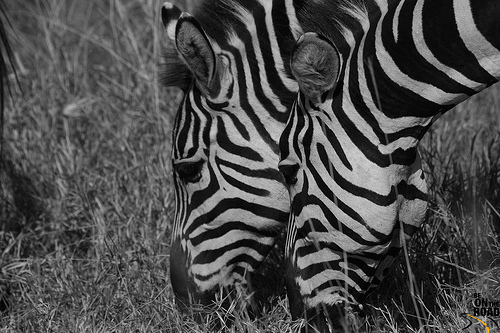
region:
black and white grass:
[43, 222, 133, 322]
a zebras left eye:
[164, 138, 211, 192]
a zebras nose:
[136, 187, 263, 325]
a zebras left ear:
[282, 43, 332, 98]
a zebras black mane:
[199, 10, 249, 27]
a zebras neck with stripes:
[370, 55, 497, 93]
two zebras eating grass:
[150, 22, 476, 312]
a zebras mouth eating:
[295, 295, 355, 328]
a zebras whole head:
[265, 111, 435, 329]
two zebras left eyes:
[157, 140, 322, 193]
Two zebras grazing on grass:
[156, 4, 379, 330]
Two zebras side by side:
[152, 5, 372, 325]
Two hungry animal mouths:
[155, 198, 401, 321]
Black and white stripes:
[340, 35, 415, 145]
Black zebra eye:
[163, 150, 211, 193]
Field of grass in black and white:
[43, 122, 141, 297]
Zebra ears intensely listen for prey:
[147, 10, 278, 105]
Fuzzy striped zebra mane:
[287, 5, 397, 56]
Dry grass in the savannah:
[35, 227, 143, 312]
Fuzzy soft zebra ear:
[286, 26, 344, 102]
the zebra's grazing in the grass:
[182, 53, 412, 306]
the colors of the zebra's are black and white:
[183, 70, 416, 298]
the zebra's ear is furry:
[178, 25, 214, 85]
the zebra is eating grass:
[62, 255, 176, 329]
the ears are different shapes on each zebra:
[175, 17, 339, 99]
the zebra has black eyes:
[172, 156, 204, 184]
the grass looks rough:
[93, 200, 163, 330]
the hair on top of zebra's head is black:
[300, 0, 363, 35]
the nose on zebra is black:
[169, 240, 190, 299]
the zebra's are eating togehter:
[161, 14, 456, 307]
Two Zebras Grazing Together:
[135, 0, 477, 330]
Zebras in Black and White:
[126, 1, 461, 331]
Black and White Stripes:
[311, 125, 386, 224]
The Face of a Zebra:
[145, 142, 276, 332]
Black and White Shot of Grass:
[2, 93, 157, 331]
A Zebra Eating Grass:
[4, 2, 255, 327]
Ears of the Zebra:
[126, 2, 416, 142]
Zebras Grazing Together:
[156, 110, 445, 330]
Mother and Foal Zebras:
[121, 7, 466, 332]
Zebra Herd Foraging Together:
[143, 12, 463, 329]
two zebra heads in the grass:
[120, 11, 453, 316]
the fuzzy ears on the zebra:
[159, 13, 351, 100]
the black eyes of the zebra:
[158, 148, 310, 198]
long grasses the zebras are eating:
[14, 25, 156, 246]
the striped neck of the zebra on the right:
[361, 15, 498, 117]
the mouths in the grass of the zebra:
[153, 258, 357, 330]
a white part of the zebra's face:
[358, 158, 381, 186]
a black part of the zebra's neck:
[376, 85, 405, 113]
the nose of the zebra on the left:
[170, 234, 194, 303]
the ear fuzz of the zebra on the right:
[301, 51, 324, 77]